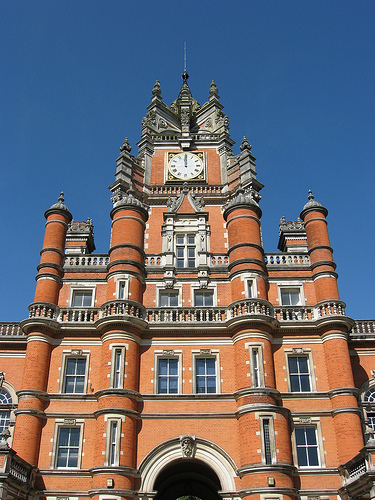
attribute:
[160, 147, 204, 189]
clock — white, round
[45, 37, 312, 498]
tower — ornate, tall, brown, browny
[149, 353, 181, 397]
window — thin, ornate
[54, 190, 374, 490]
building — red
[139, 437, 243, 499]
archway — circular, large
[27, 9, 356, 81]
sky — blue, clear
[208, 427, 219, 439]
brick — red